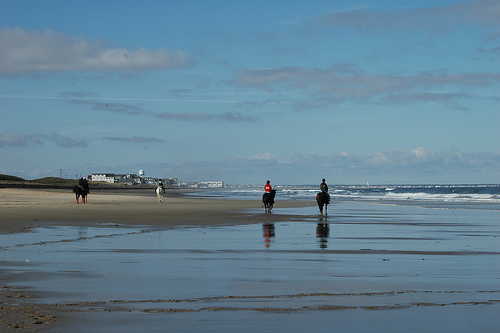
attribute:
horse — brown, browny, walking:
[260, 197, 292, 219]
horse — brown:
[65, 185, 102, 202]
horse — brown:
[311, 192, 328, 216]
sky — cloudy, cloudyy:
[105, 21, 174, 74]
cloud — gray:
[51, 38, 91, 69]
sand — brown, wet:
[107, 207, 144, 227]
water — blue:
[423, 180, 467, 208]